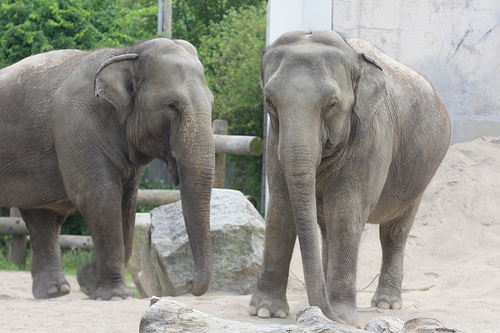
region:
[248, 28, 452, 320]
A gray elephant standing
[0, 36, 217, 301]
A gray elephant walking about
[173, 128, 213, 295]
The long trunk of a gray elephant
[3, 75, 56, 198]
The tough hide of a gray elephant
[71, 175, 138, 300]
Front legs of an elephant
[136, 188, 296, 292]
Large rock in an elephant's enclosure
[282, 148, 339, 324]
A gray elephant's trunk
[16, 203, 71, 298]
Back leg of an elephant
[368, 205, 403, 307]
Back leg of an elephant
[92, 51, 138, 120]
An elephant's floppy ear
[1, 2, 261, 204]
green leaves on trees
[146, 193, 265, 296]
surface of gray rock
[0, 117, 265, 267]
wood post on fence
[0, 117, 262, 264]
fence of zoo enclosure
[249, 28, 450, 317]
front of standing elephant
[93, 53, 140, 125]
ear on elephant head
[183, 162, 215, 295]
elephant trunk curled at the end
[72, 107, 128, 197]
wrinkled skin of elephant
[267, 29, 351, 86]
lumps on elephant head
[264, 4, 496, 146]
gray wall of enclosure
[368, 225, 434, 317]
leg of an elephant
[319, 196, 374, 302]
leg of an elephant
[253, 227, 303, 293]
leg of an elephant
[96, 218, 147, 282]
leg of an elephant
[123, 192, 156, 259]
leg of an elephant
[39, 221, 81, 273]
leg of an elephant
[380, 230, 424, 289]
a leg of an elephant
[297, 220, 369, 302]
a leg of an elephant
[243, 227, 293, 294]
a leg of an elephant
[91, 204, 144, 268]
a leg of an elephant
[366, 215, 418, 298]
a leg of an elephant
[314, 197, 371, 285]
a leg of an elephant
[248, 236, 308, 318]
a leg of an elephant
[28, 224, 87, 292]
a leg of an elephant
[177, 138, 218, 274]
Elephant has long trunk.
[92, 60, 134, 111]
Elephant has large gray ear.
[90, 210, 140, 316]
Elephant has large gray leg.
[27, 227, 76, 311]
Elephant has large gray leg.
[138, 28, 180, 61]
Black hair on top of elephant's head.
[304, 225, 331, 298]
Elephant has long gray trunk.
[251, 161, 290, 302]
Elephant has large gray leg.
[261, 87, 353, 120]
Elephant has large dark eyes.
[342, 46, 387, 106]
Elephant has large gray ears.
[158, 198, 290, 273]
Large gray rock behind elephants.